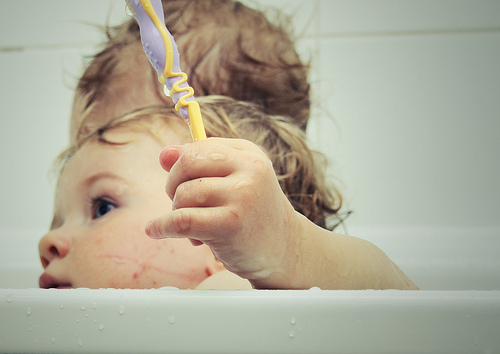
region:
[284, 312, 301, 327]
water drop on tub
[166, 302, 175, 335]
water drop on tub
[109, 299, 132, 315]
water drop on tub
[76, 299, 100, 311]
water drop on tub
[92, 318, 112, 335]
water drop on tub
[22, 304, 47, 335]
water drop on tub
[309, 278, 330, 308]
water drop on tub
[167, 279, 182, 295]
water drop on tub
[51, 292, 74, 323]
water drop on tub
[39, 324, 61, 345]
water drop on tub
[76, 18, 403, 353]
kids in a bathtub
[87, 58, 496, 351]
kdis in a bathroom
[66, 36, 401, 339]
kids that are taking a bath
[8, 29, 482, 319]
kids taking a bath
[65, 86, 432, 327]
a kid holding a toothbrush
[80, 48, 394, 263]
kids with short hair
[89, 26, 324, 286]
a purple and yellow toothrbuhq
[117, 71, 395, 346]
a kids toothbrush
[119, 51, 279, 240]
a yellow and purple toothbrush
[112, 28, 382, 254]
a toothbrush that is purple and yellow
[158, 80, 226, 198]
baby holding a tooth brush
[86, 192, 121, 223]
baby with blue eyes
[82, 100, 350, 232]
baby with blond hair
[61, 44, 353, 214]
two babies with blond hair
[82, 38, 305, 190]
two babies with wet hair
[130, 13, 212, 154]
purple and yellow tooth brush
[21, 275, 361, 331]
water on the tub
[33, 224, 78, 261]
baby with a small nose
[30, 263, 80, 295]
baby with his mouth open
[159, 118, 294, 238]
baby with wet hands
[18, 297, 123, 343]
Drops of water on bathtub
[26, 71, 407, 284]
Baby in tub playing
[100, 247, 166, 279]
red mark on baby face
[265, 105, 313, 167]
Wet blond hair on baby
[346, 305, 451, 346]
A white bathtub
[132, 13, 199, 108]
A purple and yellow toothbrush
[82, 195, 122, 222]
Dark brown eye on baby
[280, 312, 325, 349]
water droplets on tub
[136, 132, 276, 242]
baby hand is wet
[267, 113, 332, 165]
Brown and blond wet hair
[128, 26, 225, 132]
a baby holding object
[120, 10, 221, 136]
a brush holding by boy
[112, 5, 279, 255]
a boy holding brush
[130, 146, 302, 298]
hand of the boy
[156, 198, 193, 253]
fingers of the boy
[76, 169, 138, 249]
eye of the cute boy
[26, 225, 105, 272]
nose of the kid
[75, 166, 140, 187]
eye brows of the boy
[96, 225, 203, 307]
chin of the baby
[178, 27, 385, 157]
hairs of the boy